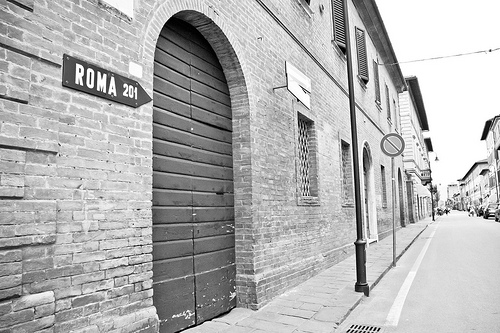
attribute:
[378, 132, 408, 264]
sign — street, parking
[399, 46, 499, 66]
wire — electric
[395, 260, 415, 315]
line — colored, light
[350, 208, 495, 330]
road — side, asphalt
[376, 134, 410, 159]
sign — round, crossing line, design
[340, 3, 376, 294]
lamp pole — street, black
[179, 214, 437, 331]
sidewalk — brick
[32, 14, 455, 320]
brick building — side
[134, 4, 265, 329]
door — wooden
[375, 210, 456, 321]
road — paved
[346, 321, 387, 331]
sewer — wholes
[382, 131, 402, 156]
sign — street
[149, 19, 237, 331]
door — garage, rounded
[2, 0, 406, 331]
building — side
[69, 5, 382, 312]
building — side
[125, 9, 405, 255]
building — side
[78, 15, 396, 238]
building — side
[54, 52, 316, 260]
building — side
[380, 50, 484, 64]
cable — dark, thin